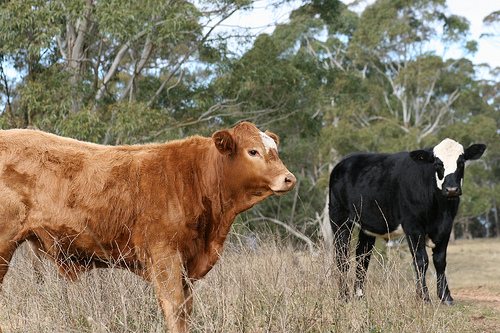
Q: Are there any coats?
A: Yes, there is a coat.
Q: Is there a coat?
A: Yes, there is a coat.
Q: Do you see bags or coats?
A: Yes, there is a coat.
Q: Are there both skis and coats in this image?
A: No, there is a coat but no skis.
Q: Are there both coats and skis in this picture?
A: No, there is a coat but no skis.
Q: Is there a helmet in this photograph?
A: No, there are no helmets.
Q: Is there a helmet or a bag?
A: No, there are no helmets or bags.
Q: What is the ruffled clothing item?
A: The clothing item is a coat.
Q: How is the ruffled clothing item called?
A: The clothing item is a coat.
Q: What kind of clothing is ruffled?
A: The clothing is a coat.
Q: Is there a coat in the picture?
A: Yes, there is a coat.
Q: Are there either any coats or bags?
A: Yes, there is a coat.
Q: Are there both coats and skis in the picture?
A: No, there is a coat but no skis.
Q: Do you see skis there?
A: No, there are no skis.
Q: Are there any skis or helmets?
A: No, there are no skis or helmets.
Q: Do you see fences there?
A: No, there are no fences.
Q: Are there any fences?
A: No, there are no fences.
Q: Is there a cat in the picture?
A: No, there are no cats.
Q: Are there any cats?
A: No, there are no cats.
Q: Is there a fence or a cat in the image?
A: No, there are no cats or fences.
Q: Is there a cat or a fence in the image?
A: No, there are no cats or fences.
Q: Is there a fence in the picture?
A: No, there are no fences.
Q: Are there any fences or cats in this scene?
A: No, there are no fences or cats.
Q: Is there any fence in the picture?
A: No, there are no fences.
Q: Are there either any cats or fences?
A: No, there are no fences or cats.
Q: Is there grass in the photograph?
A: Yes, there is grass.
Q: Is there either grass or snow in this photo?
A: Yes, there is grass.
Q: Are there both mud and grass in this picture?
A: No, there is grass but no mud.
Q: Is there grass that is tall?
A: Yes, there is tall grass.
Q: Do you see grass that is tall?
A: Yes, there is grass that is tall.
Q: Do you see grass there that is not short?
A: Yes, there is tall grass.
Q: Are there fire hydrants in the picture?
A: No, there are no fire hydrants.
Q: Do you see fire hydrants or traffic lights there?
A: No, there are no fire hydrants or traffic lights.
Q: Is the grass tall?
A: Yes, the grass is tall.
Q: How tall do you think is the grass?
A: The grass is tall.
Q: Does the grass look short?
A: No, the grass is tall.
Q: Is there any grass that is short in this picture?
A: No, there is grass but it is tall.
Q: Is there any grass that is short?
A: No, there is grass but it is tall.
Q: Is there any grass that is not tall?
A: No, there is grass but it is tall.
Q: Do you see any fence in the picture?
A: No, there are no fences.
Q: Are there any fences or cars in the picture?
A: No, there are no fences or cars.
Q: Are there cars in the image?
A: No, there are no cars.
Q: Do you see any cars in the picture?
A: No, there are no cars.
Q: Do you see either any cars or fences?
A: No, there are no cars or fences.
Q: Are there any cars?
A: No, there are no cars.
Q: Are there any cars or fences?
A: No, there are no cars or fences.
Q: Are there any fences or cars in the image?
A: No, there are no cars or fences.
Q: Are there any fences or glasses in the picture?
A: No, there are no fences or glasses.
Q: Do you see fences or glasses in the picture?
A: No, there are no fences or glasses.